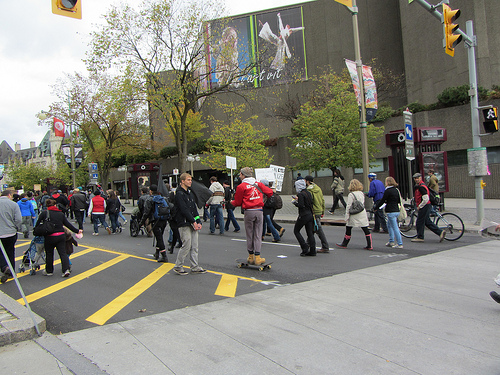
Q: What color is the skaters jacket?
A: Red.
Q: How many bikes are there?
A: One.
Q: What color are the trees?
A: Green.